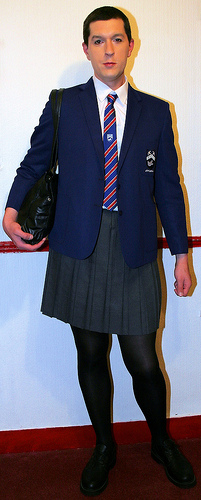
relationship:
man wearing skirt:
[2, 5, 197, 498] [39, 200, 161, 337]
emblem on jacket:
[144, 148, 155, 172] [3, 77, 198, 268]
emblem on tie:
[106, 132, 113, 142] [102, 92, 119, 210]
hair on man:
[80, 6, 136, 50] [2, 5, 197, 498]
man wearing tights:
[2, 5, 197, 498] [75, 335, 157, 405]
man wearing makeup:
[2, 5, 197, 498] [86, 18, 126, 76]